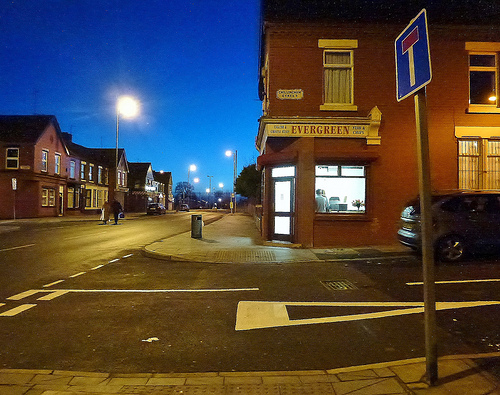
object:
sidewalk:
[1, 351, 499, 393]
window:
[42, 189, 48, 206]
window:
[5, 147, 19, 167]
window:
[41, 149, 46, 170]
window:
[55, 153, 60, 174]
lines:
[233, 294, 500, 333]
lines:
[402, 276, 498, 288]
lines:
[22, 285, 259, 294]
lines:
[2, 253, 129, 319]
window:
[325, 53, 353, 103]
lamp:
[114, 92, 143, 120]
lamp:
[188, 162, 197, 172]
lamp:
[205, 187, 211, 193]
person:
[111, 196, 125, 226]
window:
[316, 159, 369, 216]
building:
[249, 0, 500, 251]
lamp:
[223, 148, 234, 159]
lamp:
[191, 176, 201, 184]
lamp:
[217, 182, 225, 189]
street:
[4, 204, 229, 372]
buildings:
[1, 113, 175, 218]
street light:
[111, 92, 144, 213]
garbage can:
[191, 215, 204, 239]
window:
[469, 50, 500, 107]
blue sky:
[1, 0, 258, 115]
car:
[396, 188, 500, 265]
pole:
[410, 93, 443, 385]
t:
[398, 24, 423, 87]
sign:
[391, 6, 437, 101]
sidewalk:
[144, 216, 261, 265]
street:
[8, 259, 495, 364]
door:
[265, 162, 298, 242]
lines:
[0, 240, 38, 253]